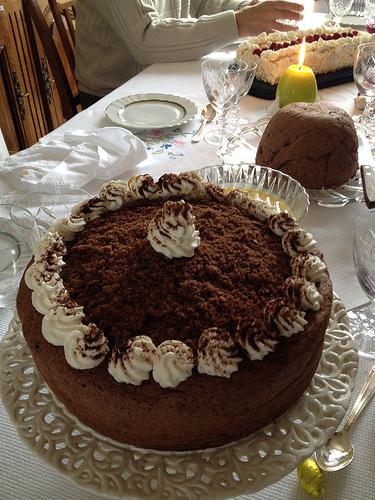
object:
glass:
[201, 58, 258, 147]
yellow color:
[276, 64, 318, 110]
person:
[72, 0, 301, 113]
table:
[0, 0, 375, 499]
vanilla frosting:
[283, 276, 323, 314]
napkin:
[0, 127, 148, 197]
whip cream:
[152, 339, 194, 389]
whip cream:
[197, 326, 243, 379]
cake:
[227, 22, 373, 102]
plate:
[0, 292, 357, 500]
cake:
[253, 101, 359, 191]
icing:
[148, 198, 202, 261]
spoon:
[314, 366, 375, 474]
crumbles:
[58, 194, 294, 345]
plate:
[106, 93, 198, 129]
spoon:
[191, 103, 217, 143]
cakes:
[16, 171, 333, 450]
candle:
[276, 65, 318, 111]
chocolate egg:
[296, 458, 321, 500]